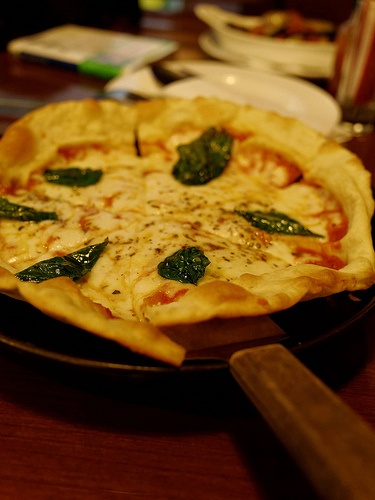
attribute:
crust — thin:
[1, 94, 374, 370]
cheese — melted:
[0, 130, 343, 326]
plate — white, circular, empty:
[155, 61, 342, 137]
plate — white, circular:
[197, 28, 336, 79]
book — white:
[6, 21, 180, 78]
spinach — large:
[172, 125, 235, 187]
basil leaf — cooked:
[235, 208, 325, 240]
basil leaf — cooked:
[16, 236, 110, 283]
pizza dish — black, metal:
[0, 184, 375, 377]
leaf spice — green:
[41, 166, 103, 188]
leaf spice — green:
[1, 196, 59, 223]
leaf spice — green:
[155, 244, 211, 285]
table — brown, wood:
[3, 0, 375, 499]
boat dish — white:
[194, 2, 340, 63]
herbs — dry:
[1, 125, 354, 326]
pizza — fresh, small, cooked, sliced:
[0, 92, 374, 367]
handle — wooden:
[227, 343, 375, 499]